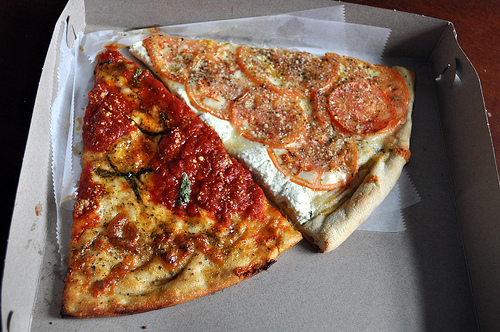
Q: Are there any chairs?
A: No, there are no chairs.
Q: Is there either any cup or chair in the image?
A: No, there are no chairs or cups.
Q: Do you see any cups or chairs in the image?
A: No, there are no chairs or cups.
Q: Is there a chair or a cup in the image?
A: No, there are no chairs or cups.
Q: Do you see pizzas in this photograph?
A: Yes, there is a pizza.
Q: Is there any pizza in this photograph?
A: Yes, there is a pizza.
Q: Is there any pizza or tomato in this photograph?
A: Yes, there is a pizza.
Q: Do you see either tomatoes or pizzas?
A: Yes, there is a pizza.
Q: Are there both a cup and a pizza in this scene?
A: No, there is a pizza but no cups.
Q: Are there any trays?
A: No, there are no trays.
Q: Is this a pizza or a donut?
A: This is a pizza.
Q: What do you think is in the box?
A: The pizza is in the box.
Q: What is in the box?
A: The pizza is in the box.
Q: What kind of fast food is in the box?
A: The food is a pizza.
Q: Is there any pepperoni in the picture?
A: Yes, there is pepperoni.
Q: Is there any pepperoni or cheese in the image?
A: Yes, there is pepperoni.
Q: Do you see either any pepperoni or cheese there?
A: Yes, there is pepperoni.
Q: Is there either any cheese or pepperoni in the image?
A: Yes, there is pepperoni.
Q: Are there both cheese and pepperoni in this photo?
A: Yes, there are both pepperoni and cheese.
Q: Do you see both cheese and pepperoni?
A: Yes, there are both pepperoni and cheese.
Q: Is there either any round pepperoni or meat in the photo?
A: Yes, there is round pepperoni.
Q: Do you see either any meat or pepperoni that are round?
A: Yes, the pepperoni is round.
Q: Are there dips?
A: No, there are no dips.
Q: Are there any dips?
A: No, there are no dips.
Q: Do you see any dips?
A: No, there are no dips.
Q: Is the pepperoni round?
A: Yes, the pepperoni is round.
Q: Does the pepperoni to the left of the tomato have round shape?
A: Yes, the pepperoni is round.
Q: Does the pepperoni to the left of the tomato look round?
A: Yes, the pepperoni is round.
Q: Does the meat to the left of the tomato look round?
A: Yes, the pepperoni is round.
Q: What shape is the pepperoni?
A: The pepperoni is round.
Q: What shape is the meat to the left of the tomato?
A: The pepperoni is round.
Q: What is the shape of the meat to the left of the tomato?
A: The pepperoni is round.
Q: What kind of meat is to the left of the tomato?
A: The meat is pepperoni.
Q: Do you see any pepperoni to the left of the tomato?
A: Yes, there is pepperoni to the left of the tomato.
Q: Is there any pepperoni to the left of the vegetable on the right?
A: Yes, there is pepperoni to the left of the tomato.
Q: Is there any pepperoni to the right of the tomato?
A: No, the pepperoni is to the left of the tomato.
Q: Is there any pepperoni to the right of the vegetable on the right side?
A: No, the pepperoni is to the left of the tomato.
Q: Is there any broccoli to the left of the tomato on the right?
A: No, there is pepperoni to the left of the tomato.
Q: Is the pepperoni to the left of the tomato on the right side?
A: Yes, the pepperoni is to the left of the tomato.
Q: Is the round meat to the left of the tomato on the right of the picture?
A: Yes, the pepperoni is to the left of the tomato.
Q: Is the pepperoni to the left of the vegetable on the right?
A: Yes, the pepperoni is to the left of the tomato.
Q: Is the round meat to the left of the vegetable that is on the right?
A: Yes, the pepperoni is to the left of the tomato.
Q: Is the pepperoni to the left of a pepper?
A: No, the pepperoni is to the left of the tomato.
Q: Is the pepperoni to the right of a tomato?
A: No, the pepperoni is to the left of a tomato.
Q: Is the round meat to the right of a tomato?
A: No, the pepperoni is to the left of a tomato.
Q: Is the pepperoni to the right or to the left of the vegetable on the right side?
A: The pepperoni is to the left of the tomato.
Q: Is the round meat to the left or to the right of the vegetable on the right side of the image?
A: The pepperoni is to the left of the tomato.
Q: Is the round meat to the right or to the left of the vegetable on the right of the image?
A: The pepperoni is to the left of the tomato.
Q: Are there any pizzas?
A: Yes, there is a pizza.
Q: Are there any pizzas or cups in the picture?
A: Yes, there is a pizza.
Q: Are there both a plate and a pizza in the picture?
A: No, there is a pizza but no plates.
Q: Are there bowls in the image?
A: No, there are no bowls.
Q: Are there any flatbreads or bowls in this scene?
A: No, there are no bowls or flatbreads.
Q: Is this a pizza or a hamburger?
A: This is a pizza.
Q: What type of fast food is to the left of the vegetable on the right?
A: The food is a pizza.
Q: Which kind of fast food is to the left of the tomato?
A: The food is a pizza.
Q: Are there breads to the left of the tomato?
A: No, there is a pizza to the left of the tomato.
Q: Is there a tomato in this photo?
A: Yes, there is a tomato.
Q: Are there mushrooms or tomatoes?
A: Yes, there is a tomato.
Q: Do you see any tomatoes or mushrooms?
A: Yes, there is a tomato.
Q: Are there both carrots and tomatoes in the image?
A: No, there is a tomato but no carrots.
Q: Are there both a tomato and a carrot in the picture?
A: No, there is a tomato but no carrots.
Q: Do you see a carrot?
A: No, there are no carrots.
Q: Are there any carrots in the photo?
A: No, there are no carrots.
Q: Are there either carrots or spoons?
A: No, there are no carrots or spoons.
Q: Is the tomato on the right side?
A: Yes, the tomato is on the right of the image.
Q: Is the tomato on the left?
A: No, the tomato is on the right of the image.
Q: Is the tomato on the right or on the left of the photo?
A: The tomato is on the right of the image.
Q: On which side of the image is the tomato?
A: The tomato is on the right of the image.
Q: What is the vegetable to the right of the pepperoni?
A: The vegetable is a tomato.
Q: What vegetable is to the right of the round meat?
A: The vegetable is a tomato.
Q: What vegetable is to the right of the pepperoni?
A: The vegetable is a tomato.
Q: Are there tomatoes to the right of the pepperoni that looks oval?
A: Yes, there is a tomato to the right of the pepperoni.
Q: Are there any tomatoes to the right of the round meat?
A: Yes, there is a tomato to the right of the pepperoni.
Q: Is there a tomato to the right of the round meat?
A: Yes, there is a tomato to the right of the pepperoni.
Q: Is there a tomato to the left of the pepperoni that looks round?
A: No, the tomato is to the right of the pepperoni.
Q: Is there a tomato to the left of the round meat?
A: No, the tomato is to the right of the pepperoni.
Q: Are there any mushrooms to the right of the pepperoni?
A: No, there is a tomato to the right of the pepperoni.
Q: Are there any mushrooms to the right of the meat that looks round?
A: No, there is a tomato to the right of the pepperoni.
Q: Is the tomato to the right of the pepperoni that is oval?
A: Yes, the tomato is to the right of the pepperoni.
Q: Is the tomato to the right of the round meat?
A: Yes, the tomato is to the right of the pepperoni.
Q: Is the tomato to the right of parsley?
A: No, the tomato is to the right of the pepperoni.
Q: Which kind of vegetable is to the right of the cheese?
A: The vegetable is a tomato.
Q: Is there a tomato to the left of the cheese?
A: No, the tomato is to the right of the cheese.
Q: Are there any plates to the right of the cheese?
A: No, there is a tomato to the right of the cheese.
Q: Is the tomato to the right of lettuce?
A: No, the tomato is to the right of the cheese.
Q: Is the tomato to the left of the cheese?
A: No, the tomato is to the right of the cheese.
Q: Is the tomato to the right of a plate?
A: No, the tomato is to the right of a pizza.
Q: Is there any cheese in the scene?
A: Yes, there is cheese.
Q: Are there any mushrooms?
A: No, there are no mushrooms.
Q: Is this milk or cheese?
A: This is cheese.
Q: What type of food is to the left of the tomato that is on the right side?
A: The food is cheese.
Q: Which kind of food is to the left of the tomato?
A: The food is cheese.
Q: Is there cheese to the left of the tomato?
A: Yes, there is cheese to the left of the tomato.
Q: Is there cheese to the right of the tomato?
A: No, the cheese is to the left of the tomato.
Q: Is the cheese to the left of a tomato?
A: Yes, the cheese is to the left of a tomato.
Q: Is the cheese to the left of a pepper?
A: No, the cheese is to the left of a tomato.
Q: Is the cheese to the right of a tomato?
A: No, the cheese is to the left of a tomato.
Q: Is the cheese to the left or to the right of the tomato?
A: The cheese is to the left of the tomato.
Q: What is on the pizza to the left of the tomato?
A: The cheese is on the pizza.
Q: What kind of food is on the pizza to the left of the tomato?
A: The food is cheese.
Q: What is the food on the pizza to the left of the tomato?
A: The food is cheese.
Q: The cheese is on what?
A: The cheese is on the pizza.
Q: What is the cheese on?
A: The cheese is on the pizza.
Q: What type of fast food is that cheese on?
A: The cheese is on the pizza.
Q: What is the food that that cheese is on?
A: The food is a pizza.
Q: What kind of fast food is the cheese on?
A: The cheese is on the pizza.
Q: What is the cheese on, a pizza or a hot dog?
A: The cheese is on a pizza.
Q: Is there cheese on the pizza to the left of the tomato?
A: Yes, there is cheese on the pizza.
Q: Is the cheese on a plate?
A: No, the cheese is on the pizza.